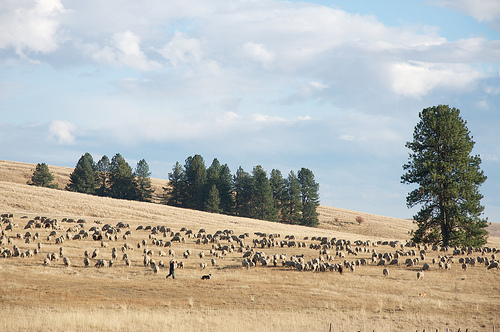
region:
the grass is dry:
[282, 292, 294, 314]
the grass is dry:
[283, 304, 300, 331]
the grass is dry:
[264, 295, 273, 314]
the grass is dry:
[262, 290, 278, 308]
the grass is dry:
[292, 325, 297, 330]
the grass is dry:
[272, 293, 287, 315]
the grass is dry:
[276, 303, 291, 320]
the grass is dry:
[268, 303, 276, 316]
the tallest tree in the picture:
[366, 72, 498, 293]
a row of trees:
[14, 144, 161, 210]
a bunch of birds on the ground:
[51, 207, 398, 284]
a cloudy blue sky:
[73, 12, 259, 110]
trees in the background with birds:
[10, 93, 235, 298]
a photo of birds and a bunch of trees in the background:
[6, 93, 497, 296]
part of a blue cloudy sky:
[297, 73, 379, 149]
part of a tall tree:
[400, 61, 495, 191]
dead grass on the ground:
[247, 280, 335, 328]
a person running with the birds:
[93, 235, 235, 322]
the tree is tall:
[447, 217, 472, 254]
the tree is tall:
[432, 223, 445, 234]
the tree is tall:
[422, 218, 438, 240]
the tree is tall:
[437, 220, 444, 231]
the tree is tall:
[433, 213, 445, 238]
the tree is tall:
[415, 207, 431, 229]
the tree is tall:
[413, 220, 429, 250]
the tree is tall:
[433, 197, 446, 215]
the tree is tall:
[433, 217, 439, 240]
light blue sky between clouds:
[409, 6, 437, 20]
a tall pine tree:
[400, 103, 485, 258]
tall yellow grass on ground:
[98, 308, 228, 328]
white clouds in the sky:
[252, 31, 335, 55]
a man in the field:
[163, 259, 176, 281]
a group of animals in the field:
[76, 225, 178, 257]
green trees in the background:
[23, 153, 335, 234]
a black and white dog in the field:
[197, 272, 212, 280]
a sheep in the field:
[417, 266, 426, 280]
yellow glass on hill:
[24, 196, 84, 209]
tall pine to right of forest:
[406, 108, 491, 258]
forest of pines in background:
[38, 144, 333, 238]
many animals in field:
[18, 231, 498, 274]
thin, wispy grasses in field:
[7, 299, 497, 319]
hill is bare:
[7, 222, 499, 315]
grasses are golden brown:
[13, 279, 499, 317]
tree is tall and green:
[401, 104, 490, 250]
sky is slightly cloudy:
[8, 6, 496, 151]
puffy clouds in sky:
[15, 13, 402, 143]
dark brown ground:
[29, 278, 344, 330]